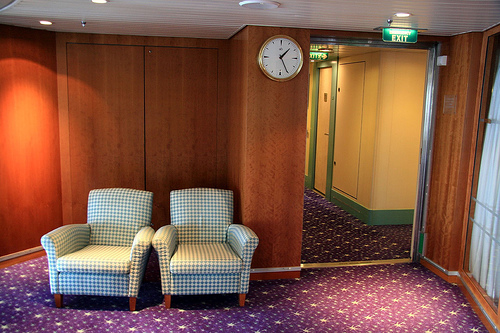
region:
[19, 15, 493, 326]
picture taken indoors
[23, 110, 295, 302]
two chairs in a room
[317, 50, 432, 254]
a mirror on the wall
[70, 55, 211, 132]
the walls are made of wood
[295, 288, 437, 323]
carpet on the floor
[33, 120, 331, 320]
two chairs next to each other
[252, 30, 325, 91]
a clock on a wall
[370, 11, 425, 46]
an exit sign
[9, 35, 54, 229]
a light on the wall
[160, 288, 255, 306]
the legs are made of wood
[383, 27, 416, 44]
green lighted exit sign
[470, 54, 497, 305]
window with a white curtain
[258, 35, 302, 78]
wall clock with gold trim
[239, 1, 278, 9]
round white object on the ceiling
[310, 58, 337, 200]
green moulding around the door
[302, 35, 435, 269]
entrance to the hall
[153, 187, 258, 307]
white and blue checkered chair with wooden feet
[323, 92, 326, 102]
gold plate on the door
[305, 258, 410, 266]
gold plate on the floor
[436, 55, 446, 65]
white box on the wall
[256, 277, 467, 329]
Maroon carpet with yellow stars.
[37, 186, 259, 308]
Two green and white plaid chairs.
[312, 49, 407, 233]
Yellow wall with green trim.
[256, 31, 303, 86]
Black and white clock.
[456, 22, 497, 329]
Window with white curtain.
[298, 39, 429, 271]
Big mirror on wall.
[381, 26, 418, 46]
Lighted green and white exit sign.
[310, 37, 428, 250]
Reflection of wall and sign in mirror.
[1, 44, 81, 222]
Light reflection on wall.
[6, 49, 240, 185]
Wood panel on wall.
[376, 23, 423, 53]
Exit sign above door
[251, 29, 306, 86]
Clock on the wall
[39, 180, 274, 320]
Two chairs beside each other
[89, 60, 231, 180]
Wall is brown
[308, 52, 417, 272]
Hallway is through the door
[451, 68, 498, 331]
Door with glass on the right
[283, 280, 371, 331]
Carpet is purple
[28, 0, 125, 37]
Two lights on the ceiling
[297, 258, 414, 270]
Gold metal doorstopper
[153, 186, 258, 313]
Chair is green and white plaid print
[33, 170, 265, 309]
two chairs in a lobby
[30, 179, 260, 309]
two gingham chairs in a room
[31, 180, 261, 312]
two checkered chairs in a room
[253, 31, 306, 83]
a clock on the wall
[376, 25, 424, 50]
a sign that says exit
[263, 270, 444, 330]
carpet on the floor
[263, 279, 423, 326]
stars in the carpet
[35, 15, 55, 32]
a light in the ceiling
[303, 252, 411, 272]
brass threshold on the floor